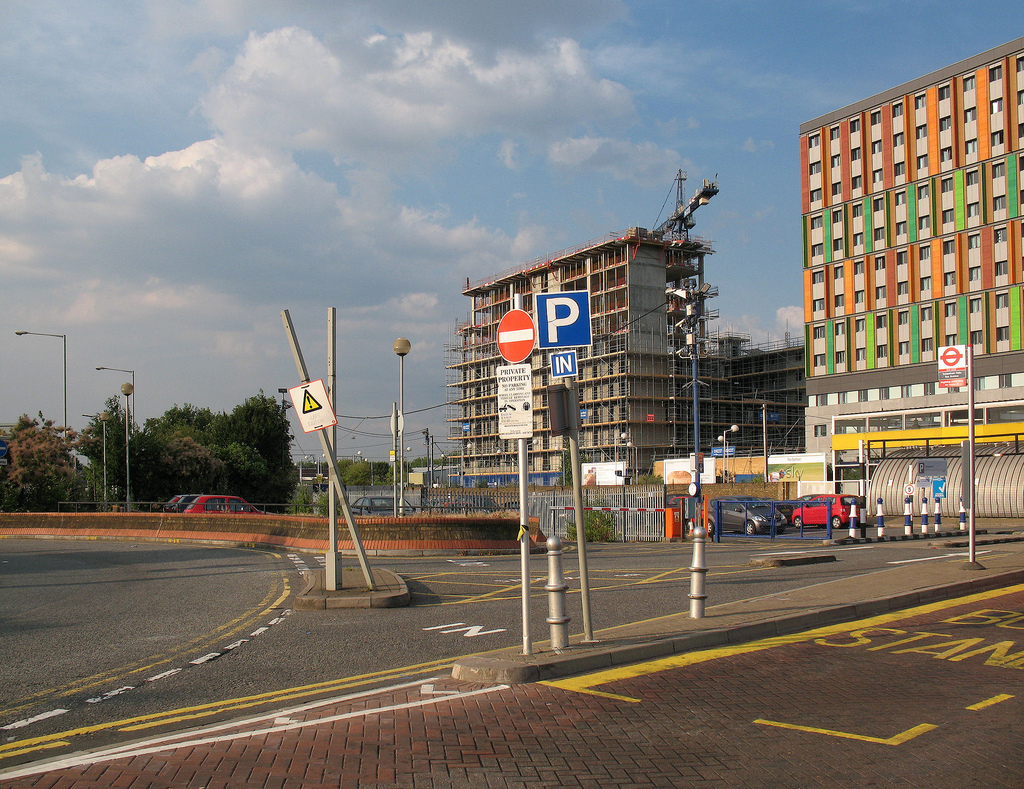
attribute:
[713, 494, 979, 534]
line — post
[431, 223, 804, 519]
building — under construction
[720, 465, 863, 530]
cars — parked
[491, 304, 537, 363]
traffic sign — round, do not enter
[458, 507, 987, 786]
spot — parking, reserved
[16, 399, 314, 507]
trees — small area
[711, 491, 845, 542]
gate — blue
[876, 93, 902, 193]
trim — orange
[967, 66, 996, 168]
trim — orange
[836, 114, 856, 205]
trim — orange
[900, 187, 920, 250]
trim — green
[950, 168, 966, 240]
trim — green